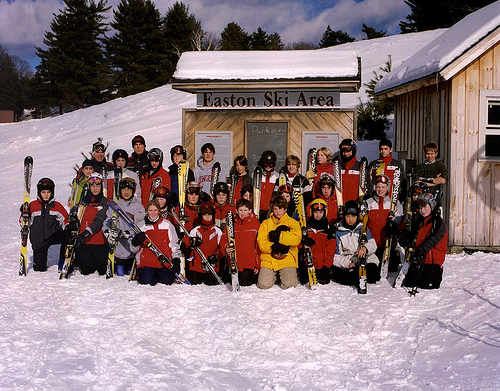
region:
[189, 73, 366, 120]
a sign at the ski lodge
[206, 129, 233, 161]
the rules of the ski mountain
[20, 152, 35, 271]
a pair of snow skis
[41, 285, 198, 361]
a pile of snow on the mountain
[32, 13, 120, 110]
a green tree in the winter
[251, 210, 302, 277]
a boy has a yellow jacket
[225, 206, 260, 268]
a boy has a red jacket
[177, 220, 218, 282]
a pair of ski poles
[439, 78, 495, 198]
a mountain ski lodge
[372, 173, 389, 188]
a pair of ski goggles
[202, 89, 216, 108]
the letter E on the sign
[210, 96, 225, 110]
the letter A on a sign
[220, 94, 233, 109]
the letter S on the sign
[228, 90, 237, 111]
the letter T on the sign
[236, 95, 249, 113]
the letter O on the sign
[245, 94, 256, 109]
the letter N on the sign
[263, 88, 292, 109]
the word "ski" on the sign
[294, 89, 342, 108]
the word "area" on the sign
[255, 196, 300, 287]
person dressed in a yellow coat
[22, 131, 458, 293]
a group that went skiing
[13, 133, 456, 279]
people standing in the snow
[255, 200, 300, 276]
a boy in a yellow coat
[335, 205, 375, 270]
a boy in a white coat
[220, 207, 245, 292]
a ski the person is holding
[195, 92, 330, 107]
a sign on the building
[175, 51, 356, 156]
a white building behind the people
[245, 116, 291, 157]
a chalk board on the building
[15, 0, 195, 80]
the trees behind the snow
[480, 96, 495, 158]
a window on the building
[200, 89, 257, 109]
the word Easton in the sign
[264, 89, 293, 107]
the word Ski on the sign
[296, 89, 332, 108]
the word Area on the sign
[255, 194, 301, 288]
a person wearing a yellow coat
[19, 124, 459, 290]
a group of skiier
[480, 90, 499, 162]
window in the house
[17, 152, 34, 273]
a skiier's equipment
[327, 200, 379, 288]
a skiier wearing white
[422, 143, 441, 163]
head on a child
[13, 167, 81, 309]
this is a person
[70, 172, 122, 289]
this is a person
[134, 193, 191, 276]
this is a person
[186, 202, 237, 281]
this is a person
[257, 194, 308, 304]
this is a person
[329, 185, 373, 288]
this is a person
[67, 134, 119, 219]
this is a person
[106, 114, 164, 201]
this is a person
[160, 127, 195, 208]
this is a person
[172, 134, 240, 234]
this is a person